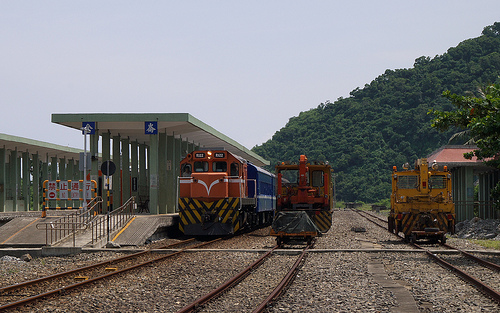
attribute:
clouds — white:
[39, 26, 143, 83]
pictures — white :
[82, 121, 160, 131]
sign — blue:
[143, 118, 157, 135]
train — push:
[175, 147, 288, 237]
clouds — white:
[32, 37, 259, 97]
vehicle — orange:
[384, 159, 457, 245]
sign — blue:
[82, 122, 94, 135]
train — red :
[176, 142, 263, 229]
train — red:
[163, 146, 293, 240]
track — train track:
[350, 212, 495, 312]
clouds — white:
[121, 3, 336, 103]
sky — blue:
[291, 24, 381, 73]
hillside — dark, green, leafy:
[248, 18, 498, 210]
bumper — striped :
[178, 197, 250, 232]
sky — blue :
[49, 4, 334, 154]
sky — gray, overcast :
[3, 10, 474, 145]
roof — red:
[426, 142, 488, 166]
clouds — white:
[2, 0, 497, 149]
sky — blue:
[1, 0, 498, 154]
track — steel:
[2, 212, 338, 308]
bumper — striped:
[179, 198, 233, 233]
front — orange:
[174, 147, 245, 237]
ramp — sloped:
[0, 210, 164, 241]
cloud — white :
[29, 33, 119, 92]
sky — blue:
[51, 20, 352, 101]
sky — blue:
[55, 20, 313, 94]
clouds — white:
[65, 46, 237, 110]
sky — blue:
[68, 21, 378, 77]